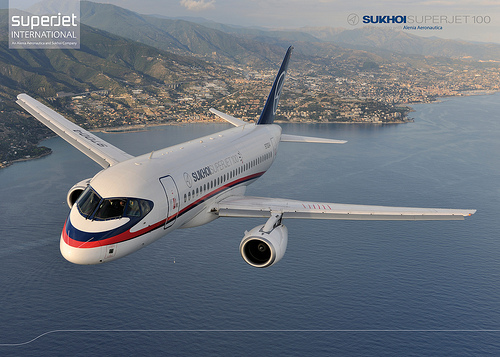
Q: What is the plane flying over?
A: Water.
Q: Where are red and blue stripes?
A: On the plane.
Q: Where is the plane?
A: In the air.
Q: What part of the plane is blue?
A: Tail.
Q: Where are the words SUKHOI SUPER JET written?
A: On the side of the plain.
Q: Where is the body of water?
A: Below the plane.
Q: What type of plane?
A: Passenger plane.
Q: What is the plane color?
A: Blue, red and white.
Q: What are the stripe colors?
A: Red and blue.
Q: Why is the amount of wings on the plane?
A: Two wings.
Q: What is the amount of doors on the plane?
A: Two doors.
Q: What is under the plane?
A: Water.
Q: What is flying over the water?
A: A jet.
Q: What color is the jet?
A: White, blue, and red.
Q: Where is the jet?
A: In the air.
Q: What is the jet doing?
A: Carrying people.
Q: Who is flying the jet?
A: The pilot.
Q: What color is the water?
A: Blue.